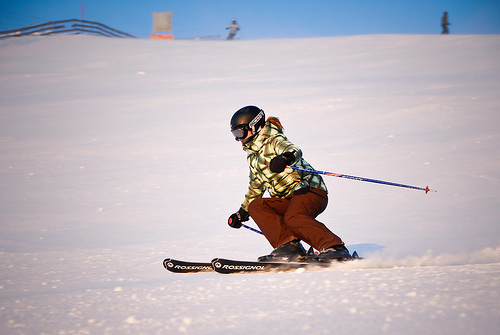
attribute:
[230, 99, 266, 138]
helmet — black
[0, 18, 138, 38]
fence — wooden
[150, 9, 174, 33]
sign — white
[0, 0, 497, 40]
sky — blue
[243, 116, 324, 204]
sweatshirt — plaid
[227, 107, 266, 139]
helmet — shiny, brown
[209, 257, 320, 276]
ski — black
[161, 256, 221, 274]
ski — black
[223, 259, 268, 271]
letters — white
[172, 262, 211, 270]
letters — white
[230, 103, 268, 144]
helmet — black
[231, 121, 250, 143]
goggles — black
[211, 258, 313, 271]
ski — black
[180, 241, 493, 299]
snow — white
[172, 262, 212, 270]
word — white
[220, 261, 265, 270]
word — white